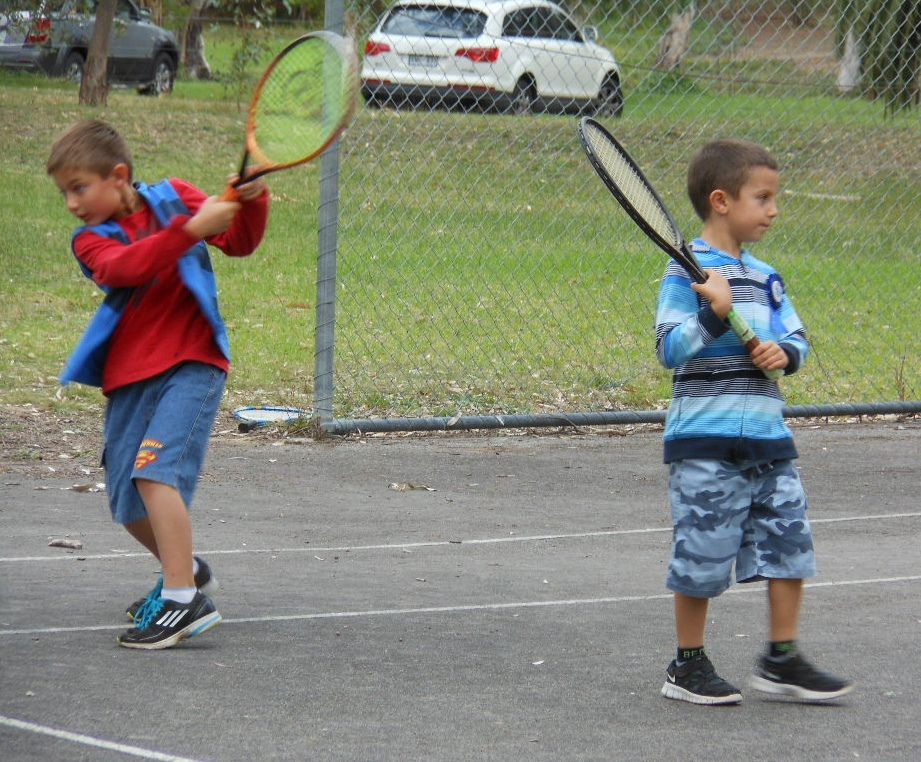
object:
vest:
[60, 178, 231, 385]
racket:
[577, 116, 709, 285]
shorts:
[667, 458, 814, 598]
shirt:
[74, 178, 270, 398]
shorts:
[98, 360, 227, 525]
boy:
[45, 120, 267, 650]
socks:
[162, 559, 200, 604]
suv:
[361, 0, 625, 120]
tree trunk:
[79, 1, 116, 107]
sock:
[162, 586, 199, 604]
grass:
[339, 111, 648, 403]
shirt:
[655, 237, 809, 464]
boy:
[655, 138, 856, 705]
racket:
[247, 30, 359, 170]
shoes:
[118, 556, 224, 649]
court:
[0, 417, 915, 758]